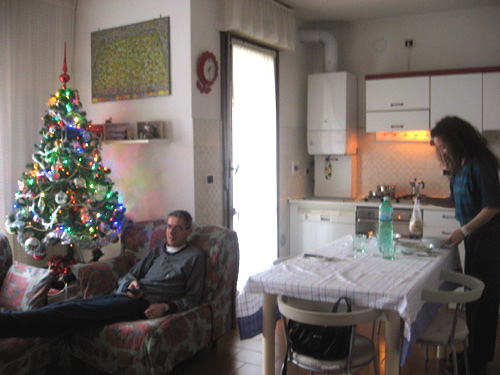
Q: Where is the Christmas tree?
A: In the corner.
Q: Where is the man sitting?
A: In a chair.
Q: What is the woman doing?
A: Setting a table.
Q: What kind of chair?
A: Kitchen.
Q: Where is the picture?
A: On the wall.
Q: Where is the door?
A: Kitchen.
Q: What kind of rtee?
A: Christmas.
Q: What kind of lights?
A: Christmas.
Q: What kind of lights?
A: Christmas.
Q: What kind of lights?
A: Christmas.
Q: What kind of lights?
A: Christmas.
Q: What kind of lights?
A: Christmas.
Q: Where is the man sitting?
A: Chair.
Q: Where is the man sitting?
A: Chair.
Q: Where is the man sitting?
A: Chair.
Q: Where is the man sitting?
A: Chair.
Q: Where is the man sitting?
A: Chair.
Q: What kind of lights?
A: Christmas.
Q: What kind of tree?
A: Christmas.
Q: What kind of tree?
A: Christmas.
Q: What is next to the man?
A: A Christmas tree.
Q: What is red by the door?
A: A clock.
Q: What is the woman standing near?
A: A table.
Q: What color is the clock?
A: Red.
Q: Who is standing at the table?
A: A woman.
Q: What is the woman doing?
A: Arranging the table.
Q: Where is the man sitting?
A: On the sofa chair.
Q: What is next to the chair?
A: Christmas tree.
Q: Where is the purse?
A: On the dining table chair.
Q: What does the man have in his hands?
A: A remote.